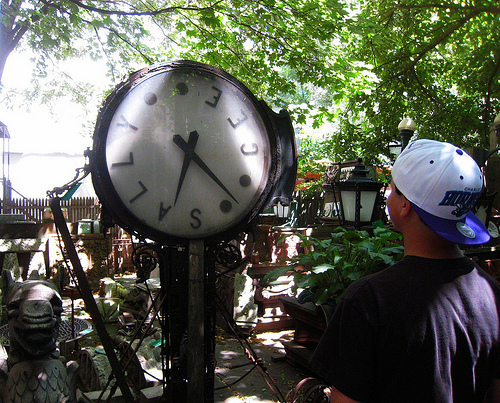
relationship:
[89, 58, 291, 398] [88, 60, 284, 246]
there is a clock clock round clock is large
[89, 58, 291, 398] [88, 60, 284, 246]
clock is on stand stand black clock is large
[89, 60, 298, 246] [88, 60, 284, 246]
clock is black clock has white face clock is large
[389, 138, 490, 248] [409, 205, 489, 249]
hat cap backwards cap has purple bill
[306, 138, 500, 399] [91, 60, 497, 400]
there is a boy re a clock boy looking at clock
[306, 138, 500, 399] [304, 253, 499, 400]
there is a boy re a tee shirt tee shirt is dark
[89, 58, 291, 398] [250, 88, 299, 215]
there is a clock clock has parts clock has parts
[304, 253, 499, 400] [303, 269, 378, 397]
there is a shirt re shirts part there is shirts part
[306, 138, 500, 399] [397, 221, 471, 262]
there is a boy re a neck boy has a neck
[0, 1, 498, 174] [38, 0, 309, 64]
there is a tree re tree branch there is tree branch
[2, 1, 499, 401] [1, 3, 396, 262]
there is a snap snap has background snap back has a part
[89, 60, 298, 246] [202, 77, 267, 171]
there is a surface surface has a part surface has a part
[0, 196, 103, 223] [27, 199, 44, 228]
picket fence fence has a part fence has a part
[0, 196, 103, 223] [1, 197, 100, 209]
picket fence fence has top fence has top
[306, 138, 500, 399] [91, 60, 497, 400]
there is a young man re a clock man looking at clock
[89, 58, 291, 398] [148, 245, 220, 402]
there is metal clock clock on a pole clock has a pole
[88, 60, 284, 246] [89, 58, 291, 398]
clock is large clock has a face there is a clock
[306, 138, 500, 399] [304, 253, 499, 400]
there is a man re a tee shirt tee shirt is black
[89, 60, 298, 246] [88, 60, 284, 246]
clock is large clock has a face clock is large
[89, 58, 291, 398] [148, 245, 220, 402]
clock has a pole pole large clock has a pole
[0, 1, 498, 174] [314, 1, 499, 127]
there is an oak tree large leaves on tree leafs are green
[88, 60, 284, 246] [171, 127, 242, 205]
clock is large re a clock black clock hands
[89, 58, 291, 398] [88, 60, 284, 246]
there is a clock clock has a face clock is large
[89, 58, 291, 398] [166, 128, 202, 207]
there is a clock clock has a hand clock has a hand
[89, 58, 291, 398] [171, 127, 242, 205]
there is a clock clock has black hand clock has black hand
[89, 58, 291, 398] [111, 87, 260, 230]
there is a clock re are letters letters are black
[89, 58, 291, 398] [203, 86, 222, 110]
there is a clock clock has a letter letter is black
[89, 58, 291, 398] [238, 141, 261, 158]
there is a clock re a letter letter is black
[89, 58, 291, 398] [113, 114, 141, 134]
there is a clock clock has a letter letter is black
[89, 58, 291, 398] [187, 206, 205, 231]
there is a clock clock has a letter letter is black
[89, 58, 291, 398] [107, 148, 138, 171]
there is a clock clock has a letter letter is black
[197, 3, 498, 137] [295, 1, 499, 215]
leaves on there is an oak tree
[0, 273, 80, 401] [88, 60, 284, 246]
sculpture beside clock is large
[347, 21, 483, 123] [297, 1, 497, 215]
leaves on tree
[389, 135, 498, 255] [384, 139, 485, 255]
hat on head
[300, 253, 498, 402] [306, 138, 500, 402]
there is a shirt on a there is a man